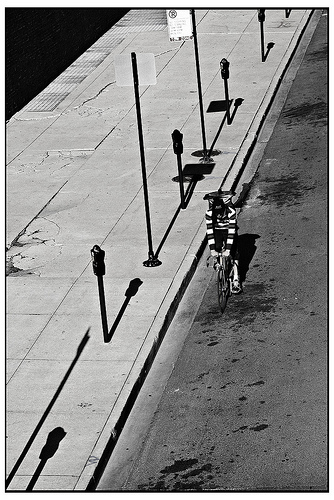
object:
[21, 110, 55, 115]
crack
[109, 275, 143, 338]
shadow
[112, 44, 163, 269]
traffic sign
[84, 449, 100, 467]
graffiti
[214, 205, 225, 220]
face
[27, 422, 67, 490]
shadow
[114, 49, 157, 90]
lamp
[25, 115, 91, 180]
piece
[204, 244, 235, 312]
bike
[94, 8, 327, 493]
road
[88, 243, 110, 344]
parking meter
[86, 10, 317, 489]
curb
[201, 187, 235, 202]
cap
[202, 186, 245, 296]
guy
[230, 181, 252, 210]
smudge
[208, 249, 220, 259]
hand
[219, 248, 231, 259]
hand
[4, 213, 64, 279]
cracked hole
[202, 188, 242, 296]
girl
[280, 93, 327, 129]
marks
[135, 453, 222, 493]
stains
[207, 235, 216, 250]
striped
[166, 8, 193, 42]
sign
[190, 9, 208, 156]
pole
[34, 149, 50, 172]
cracks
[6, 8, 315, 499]
sidewalk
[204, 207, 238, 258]
shirt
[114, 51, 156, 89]
reverse side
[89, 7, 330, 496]
street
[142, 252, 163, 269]
base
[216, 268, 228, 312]
tire